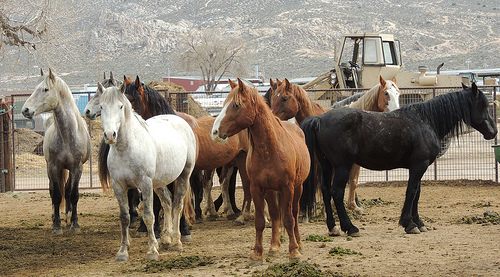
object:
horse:
[21, 68, 91, 235]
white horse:
[97, 82, 197, 259]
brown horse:
[205, 77, 314, 265]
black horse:
[300, 82, 500, 238]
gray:
[380, 68, 393, 77]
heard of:
[15, 60, 500, 268]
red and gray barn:
[159, 73, 261, 92]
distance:
[58, 39, 87, 64]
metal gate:
[7, 91, 98, 192]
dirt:
[364, 218, 378, 226]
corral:
[0, 85, 500, 277]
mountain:
[0, 10, 223, 76]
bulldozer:
[299, 27, 475, 109]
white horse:
[80, 96, 230, 230]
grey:
[72, 132, 85, 146]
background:
[0, 0, 500, 97]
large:
[7, 84, 498, 191]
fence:
[3, 84, 496, 191]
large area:
[0, 190, 500, 277]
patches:
[314, 240, 500, 277]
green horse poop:
[327, 245, 354, 256]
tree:
[0, 1, 55, 52]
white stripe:
[196, 80, 232, 144]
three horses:
[21, 66, 200, 265]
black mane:
[118, 81, 178, 116]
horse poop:
[467, 201, 500, 209]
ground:
[0, 181, 500, 277]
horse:
[94, 82, 199, 258]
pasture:
[0, 185, 113, 277]